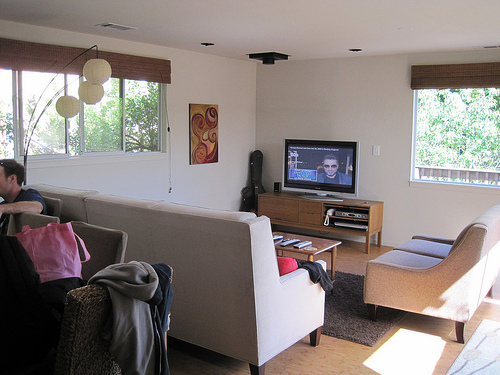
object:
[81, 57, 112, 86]
light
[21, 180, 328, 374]
couch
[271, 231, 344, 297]
coffee stand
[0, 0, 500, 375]
living room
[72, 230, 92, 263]
handles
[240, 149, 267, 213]
case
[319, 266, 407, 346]
area rug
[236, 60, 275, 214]
corner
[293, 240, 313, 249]
remote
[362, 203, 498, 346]
love seat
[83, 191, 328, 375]
sofa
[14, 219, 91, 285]
pink bag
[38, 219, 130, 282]
chair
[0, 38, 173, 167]
windows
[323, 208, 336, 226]
telephone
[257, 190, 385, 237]
shelf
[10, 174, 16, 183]
ear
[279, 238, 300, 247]
remote control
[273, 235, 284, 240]
remote control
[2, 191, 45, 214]
arm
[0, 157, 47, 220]
man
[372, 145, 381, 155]
panel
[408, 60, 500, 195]
windows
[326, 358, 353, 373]
floors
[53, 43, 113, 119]
floor lamp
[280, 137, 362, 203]
television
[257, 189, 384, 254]
console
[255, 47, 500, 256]
wall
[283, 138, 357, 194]
screen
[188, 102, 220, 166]
painting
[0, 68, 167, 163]
row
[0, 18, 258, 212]
wall